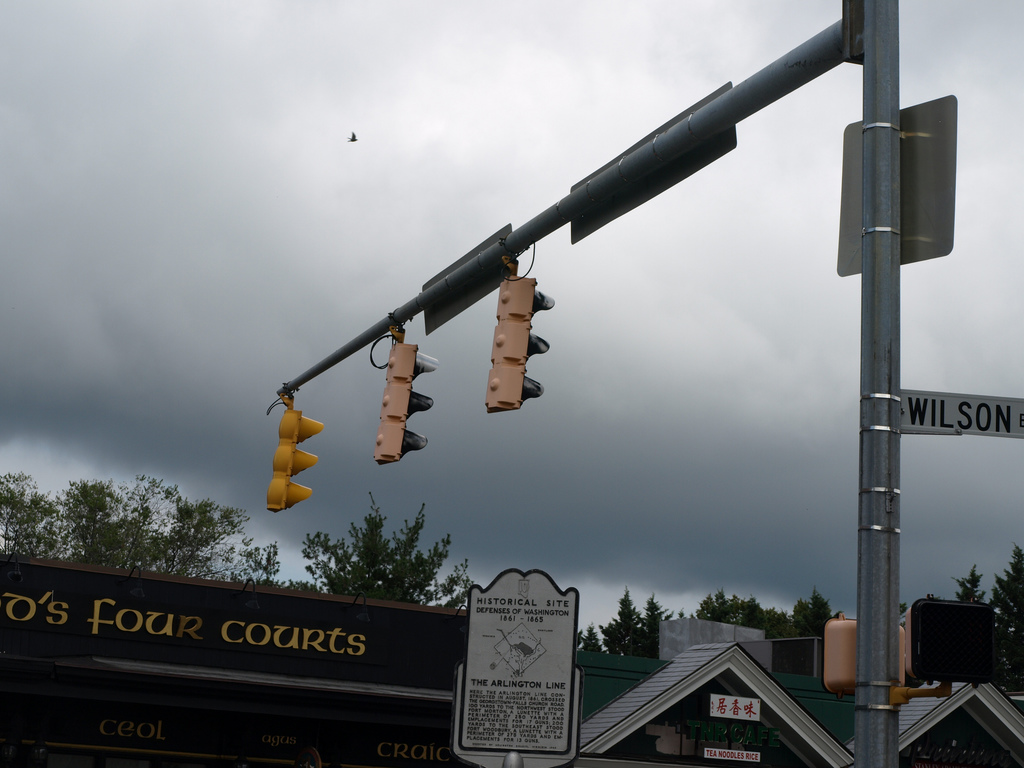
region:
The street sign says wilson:
[890, 365, 1021, 451]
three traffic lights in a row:
[256, 250, 570, 523]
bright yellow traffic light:
[256, 375, 329, 530]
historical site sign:
[455, 551, 582, 755]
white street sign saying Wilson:
[897, 384, 1019, 441]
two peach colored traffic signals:
[348, 245, 563, 479]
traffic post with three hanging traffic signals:
[231, 4, 918, 748]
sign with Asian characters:
[708, 686, 765, 731]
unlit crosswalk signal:
[904, 590, 1007, 690]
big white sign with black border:
[451, 557, 585, 763]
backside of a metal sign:
[822, 83, 971, 284]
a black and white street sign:
[895, 373, 1022, 441]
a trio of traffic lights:
[265, 250, 642, 501]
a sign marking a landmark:
[467, 566, 560, 764]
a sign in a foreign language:
[707, 686, 774, 741]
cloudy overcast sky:
[632, 165, 838, 570]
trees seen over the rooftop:
[1, 455, 467, 610]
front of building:
[16, 560, 514, 764]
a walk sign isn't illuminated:
[813, 601, 1000, 697]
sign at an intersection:
[193, 0, 917, 760]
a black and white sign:
[461, 559, 601, 765]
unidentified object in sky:
[336, 120, 368, 153]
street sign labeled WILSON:
[892, 384, 1019, 442]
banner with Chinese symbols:
[705, 686, 760, 724]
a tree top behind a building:
[303, 471, 478, 605]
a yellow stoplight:
[269, 386, 326, 517]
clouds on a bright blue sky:
[0, 354, 248, 463]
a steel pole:
[864, 6, 896, 766]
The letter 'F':
[88, 591, 118, 649]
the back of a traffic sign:
[837, 95, 958, 282]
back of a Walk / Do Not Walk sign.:
[819, 606, 925, 693]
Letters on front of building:
[1, 585, 393, 663]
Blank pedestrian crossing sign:
[887, 589, 1012, 704]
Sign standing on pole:
[430, 551, 617, 760]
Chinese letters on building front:
[691, 686, 781, 760]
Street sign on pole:
[882, 377, 1015, 442]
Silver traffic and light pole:
[840, 42, 918, 754]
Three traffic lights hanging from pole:
[216, 273, 555, 514]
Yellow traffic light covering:
[251, 386, 331, 519]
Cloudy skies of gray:
[2, 98, 272, 359]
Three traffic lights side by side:
[233, 308, 582, 517]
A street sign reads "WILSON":
[881, 370, 1017, 465]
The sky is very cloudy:
[24, 11, 366, 313]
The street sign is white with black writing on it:
[890, 365, 1012, 451]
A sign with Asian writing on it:
[695, 668, 779, 738]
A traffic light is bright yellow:
[249, 396, 317, 536]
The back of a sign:
[806, 92, 981, 320]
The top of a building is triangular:
[615, 616, 832, 753]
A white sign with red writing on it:
[701, 684, 771, 735]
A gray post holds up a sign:
[827, 282, 944, 741]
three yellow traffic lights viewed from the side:
[242, 252, 585, 589]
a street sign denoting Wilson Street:
[859, 370, 1022, 454]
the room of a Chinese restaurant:
[562, 610, 857, 763]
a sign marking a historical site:
[443, 540, 614, 766]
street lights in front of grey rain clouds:
[43, 53, 718, 560]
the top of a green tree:
[294, 488, 492, 622]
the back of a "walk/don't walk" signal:
[814, 604, 931, 709]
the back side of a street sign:
[815, 57, 986, 324]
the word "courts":
[198, 595, 396, 688]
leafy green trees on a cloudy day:
[0, 442, 263, 569]